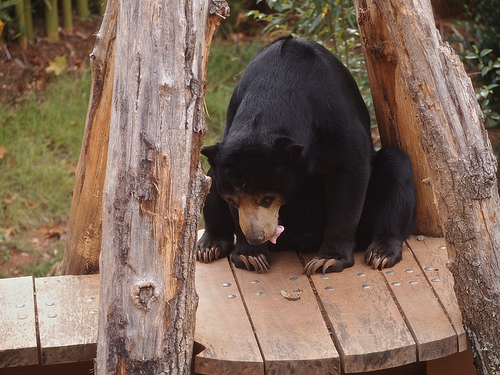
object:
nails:
[301, 257, 336, 274]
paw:
[301, 247, 354, 275]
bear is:
[192, 32, 422, 276]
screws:
[221, 267, 451, 299]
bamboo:
[2, 2, 100, 47]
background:
[0, 1, 500, 56]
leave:
[461, 34, 495, 64]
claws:
[193, 241, 400, 277]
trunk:
[95, 1, 212, 375]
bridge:
[0, 235, 468, 374]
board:
[192, 256, 459, 349]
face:
[216, 174, 287, 247]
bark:
[119, 8, 204, 373]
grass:
[0, 56, 91, 219]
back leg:
[301, 163, 371, 276]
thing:
[268, 222, 288, 245]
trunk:
[354, 1, 500, 374]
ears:
[200, 141, 223, 160]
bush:
[253, 0, 357, 34]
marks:
[125, 142, 192, 280]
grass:
[209, 33, 249, 107]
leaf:
[36, 226, 70, 248]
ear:
[198, 140, 224, 165]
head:
[198, 127, 312, 247]